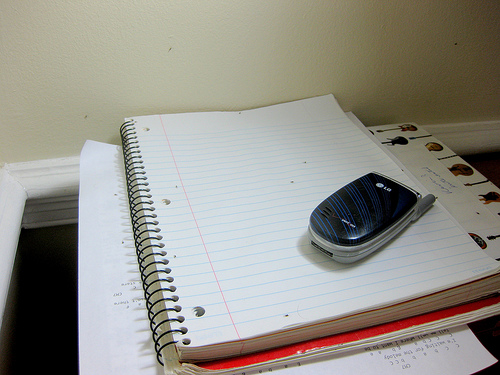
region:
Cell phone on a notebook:
[290, 141, 443, 272]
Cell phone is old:
[300, 160, 440, 275]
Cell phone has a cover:
[290, 160, 445, 272]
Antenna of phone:
[415, 182, 441, 214]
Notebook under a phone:
[115, 83, 496, 366]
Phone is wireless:
[302, 157, 443, 272]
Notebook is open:
[95, 78, 497, 370]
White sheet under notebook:
[62, 131, 494, 373]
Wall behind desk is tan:
[10, 6, 491, 156]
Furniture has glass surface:
[0, 100, 497, 371]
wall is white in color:
[31, 30, 142, 86]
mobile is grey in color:
[291, 170, 436, 262]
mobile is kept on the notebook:
[169, 140, 441, 322]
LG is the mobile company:
[314, 157, 421, 276]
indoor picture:
[25, 93, 470, 328]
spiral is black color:
[118, 129, 194, 322]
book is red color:
[191, 283, 478, 361]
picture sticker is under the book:
[399, 112, 484, 209]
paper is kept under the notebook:
[61, 184, 237, 336]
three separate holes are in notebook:
[131, 108, 224, 361]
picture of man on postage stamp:
[449, 154, 480, 183]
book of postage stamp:
[386, 116, 493, 189]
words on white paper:
[104, 282, 141, 319]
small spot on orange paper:
[295, 348, 342, 362]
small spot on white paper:
[277, 310, 302, 322]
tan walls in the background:
[230, 10, 435, 68]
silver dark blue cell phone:
[298, 164, 448, 262]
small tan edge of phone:
[420, 189, 446, 211]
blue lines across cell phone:
[322, 187, 374, 242]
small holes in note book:
[157, 187, 197, 219]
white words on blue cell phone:
[330, 212, 365, 232]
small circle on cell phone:
[375, 180, 385, 189]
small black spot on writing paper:
[277, 304, 309, 329]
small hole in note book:
[188, 305, 220, 324]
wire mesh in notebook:
[138, 307, 199, 351]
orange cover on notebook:
[259, 350, 304, 359]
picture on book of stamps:
[447, 157, 479, 191]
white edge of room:
[2, 158, 58, 203]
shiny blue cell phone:
[305, 157, 447, 284]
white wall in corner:
[112, 18, 313, 68]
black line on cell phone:
[339, 186, 360, 210]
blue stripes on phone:
[322, 196, 359, 249]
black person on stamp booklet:
[382, 126, 417, 160]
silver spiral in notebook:
[143, 303, 190, 328]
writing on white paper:
[105, 237, 149, 294]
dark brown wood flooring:
[34, 234, 69, 349]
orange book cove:
[296, 341, 358, 352]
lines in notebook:
[200, 162, 285, 234]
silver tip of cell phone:
[415, 181, 440, 223]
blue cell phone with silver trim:
[303, 160, 450, 281]